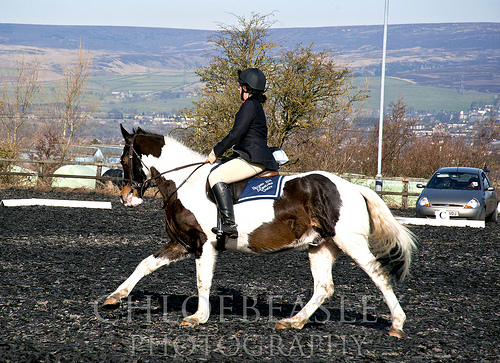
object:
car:
[411, 162, 500, 226]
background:
[20, 19, 143, 77]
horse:
[89, 118, 421, 342]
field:
[0, 186, 500, 363]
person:
[199, 65, 282, 242]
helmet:
[234, 66, 268, 91]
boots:
[211, 180, 238, 236]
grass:
[119, 78, 159, 90]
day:
[0, 0, 500, 363]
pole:
[372, 0, 392, 184]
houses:
[455, 109, 468, 121]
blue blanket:
[235, 171, 286, 204]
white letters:
[250, 178, 274, 193]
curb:
[405, 214, 485, 231]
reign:
[139, 157, 223, 198]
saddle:
[204, 172, 287, 205]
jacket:
[211, 97, 283, 170]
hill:
[403, 22, 500, 80]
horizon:
[0, 16, 500, 27]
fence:
[0, 158, 414, 210]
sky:
[0, 0, 500, 30]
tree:
[34, 34, 110, 188]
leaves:
[287, 74, 306, 88]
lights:
[419, 196, 433, 208]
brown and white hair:
[305, 174, 352, 230]